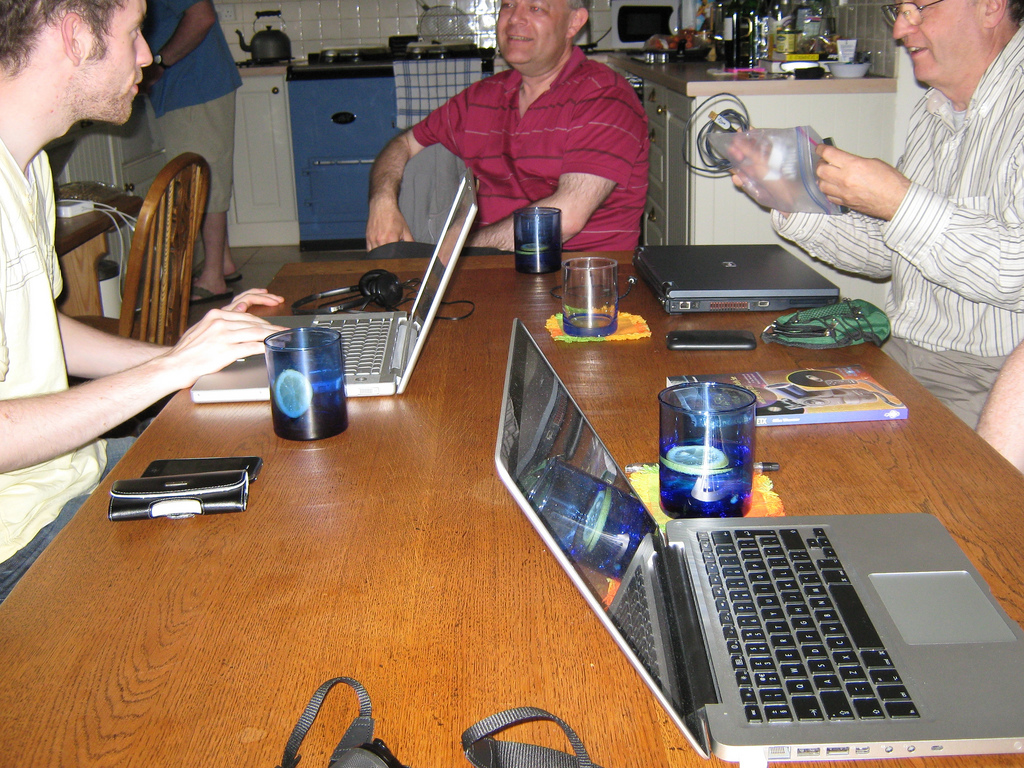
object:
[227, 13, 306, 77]
teapot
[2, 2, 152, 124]
head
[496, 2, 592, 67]
head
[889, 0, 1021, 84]
head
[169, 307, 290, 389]
hand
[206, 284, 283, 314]
hand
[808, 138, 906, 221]
hand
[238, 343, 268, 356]
finger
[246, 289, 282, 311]
finger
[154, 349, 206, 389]
wrist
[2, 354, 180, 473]
arm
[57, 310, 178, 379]
arm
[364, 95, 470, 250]
arm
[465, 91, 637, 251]
arm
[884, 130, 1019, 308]
arm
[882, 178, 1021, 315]
sleeve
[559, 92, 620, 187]
sleeve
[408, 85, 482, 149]
sleeve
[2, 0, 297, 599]
man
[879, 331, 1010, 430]
pants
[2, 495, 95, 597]
pants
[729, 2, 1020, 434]
man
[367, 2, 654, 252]
man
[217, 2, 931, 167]
wall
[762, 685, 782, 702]
key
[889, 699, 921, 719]
key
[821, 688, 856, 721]
key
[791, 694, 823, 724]
key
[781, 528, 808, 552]
key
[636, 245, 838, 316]
laptop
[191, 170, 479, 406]
laptop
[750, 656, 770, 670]
key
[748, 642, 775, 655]
key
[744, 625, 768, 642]
key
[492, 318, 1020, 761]
laptop